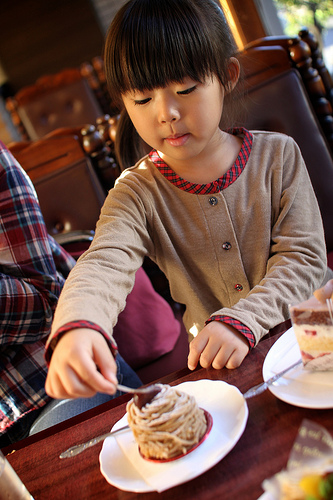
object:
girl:
[42, 0, 327, 402]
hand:
[42, 327, 118, 401]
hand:
[187, 322, 249, 373]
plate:
[98, 377, 248, 493]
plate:
[261, 325, 332, 410]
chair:
[78, 38, 332, 318]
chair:
[15, 125, 122, 241]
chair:
[5, 63, 110, 145]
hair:
[104, 1, 238, 173]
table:
[8, 328, 332, 500]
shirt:
[42, 127, 328, 347]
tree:
[271, 0, 332, 51]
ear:
[221, 53, 239, 94]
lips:
[162, 131, 189, 149]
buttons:
[208, 196, 244, 295]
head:
[105, 2, 240, 159]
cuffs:
[42, 313, 255, 370]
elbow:
[310, 255, 330, 284]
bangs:
[104, 2, 213, 96]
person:
[1, 141, 144, 449]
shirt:
[1, 142, 77, 434]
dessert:
[289, 287, 331, 375]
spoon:
[116, 384, 160, 410]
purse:
[69, 248, 181, 368]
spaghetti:
[125, 380, 207, 460]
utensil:
[58, 421, 129, 461]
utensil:
[245, 359, 301, 399]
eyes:
[133, 84, 198, 105]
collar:
[148, 125, 253, 193]